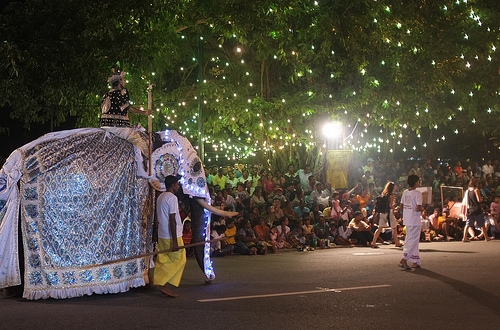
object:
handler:
[96, 71, 154, 180]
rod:
[145, 82, 154, 172]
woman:
[399, 171, 432, 266]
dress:
[397, 188, 422, 265]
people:
[459, 177, 494, 244]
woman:
[398, 172, 427, 273]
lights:
[450, 127, 460, 137]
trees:
[4, 2, 498, 185]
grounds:
[440, 120, 460, 150]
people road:
[162, 170, 497, 326]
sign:
[321, 148, 353, 189]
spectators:
[182, 157, 498, 251]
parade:
[2, 60, 457, 327]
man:
[149, 175, 187, 300]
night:
[15, 12, 498, 328]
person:
[275, 216, 291, 242]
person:
[336, 219, 358, 244]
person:
[302, 217, 317, 244]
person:
[249, 186, 267, 210]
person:
[272, 189, 287, 204]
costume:
[0, 127, 218, 301]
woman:
[396, 176, 424, 273]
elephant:
[0, 126, 239, 301]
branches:
[258, 55, 266, 103]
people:
[366, 180, 402, 250]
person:
[98, 64, 154, 181]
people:
[394, 174, 425, 274]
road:
[2, 233, 497, 329]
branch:
[200, 58, 208, 84]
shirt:
[155, 193, 188, 240]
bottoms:
[151, 236, 187, 289]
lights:
[234, 47, 243, 56]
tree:
[131, 1, 485, 187]